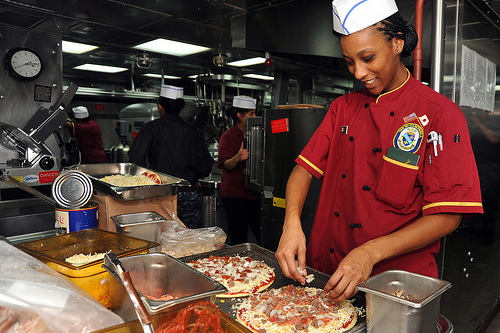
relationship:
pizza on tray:
[235, 283, 357, 332] [175, 239, 366, 332]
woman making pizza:
[273, 0, 483, 305] [235, 283, 357, 332]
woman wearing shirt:
[273, 0, 483, 305] [293, 67, 486, 286]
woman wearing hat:
[273, 0, 483, 305] [332, 0, 399, 38]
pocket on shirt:
[372, 153, 419, 211] [293, 67, 486, 286]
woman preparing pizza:
[273, 0, 483, 305] [235, 283, 357, 332]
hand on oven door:
[235, 140, 249, 161] [243, 115, 263, 194]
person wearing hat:
[127, 84, 216, 228] [159, 83, 184, 101]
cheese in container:
[65, 249, 113, 265] [16, 227, 161, 308]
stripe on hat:
[333, 0, 371, 35] [332, 0, 399, 38]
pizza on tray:
[185, 254, 275, 299] [175, 239, 366, 332]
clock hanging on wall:
[4, 45, 44, 81] [0, 22, 62, 170]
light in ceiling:
[130, 36, 212, 59] [1, 1, 286, 87]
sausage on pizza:
[294, 320, 305, 330] [235, 283, 357, 332]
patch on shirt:
[393, 121, 424, 153] [293, 67, 486, 286]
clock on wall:
[4, 45, 44, 81] [0, 22, 62, 170]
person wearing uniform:
[218, 95, 267, 244] [216, 125, 263, 199]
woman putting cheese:
[273, 0, 483, 305] [298, 266, 317, 283]